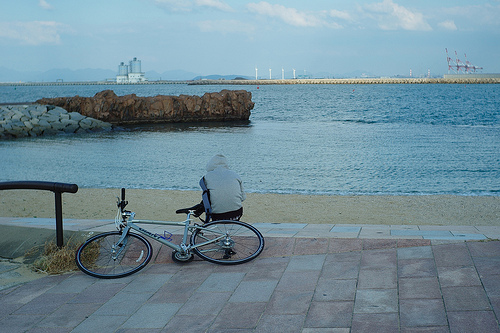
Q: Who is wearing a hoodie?
A: A person.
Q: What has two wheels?
A: A bicycle.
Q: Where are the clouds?
A: In the sky.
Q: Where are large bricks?
A: On the ground.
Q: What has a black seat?
A: The bicycle.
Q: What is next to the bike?
A: A railing.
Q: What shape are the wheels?
A: Round.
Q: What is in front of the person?
A: Sand.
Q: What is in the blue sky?
A: Clouds.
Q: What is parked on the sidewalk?
A: Bicycle.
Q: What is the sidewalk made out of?
A: Brick.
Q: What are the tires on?
A: Bike.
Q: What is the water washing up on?
A: Sand.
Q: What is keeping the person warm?
A: Sweatshirt.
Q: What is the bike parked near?
A: Railing.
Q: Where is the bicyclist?
A: Beach.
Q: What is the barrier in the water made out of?
A: Rocks.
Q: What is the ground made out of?
A: Bricks.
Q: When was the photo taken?
A: Daytime.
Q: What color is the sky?
A: Blue.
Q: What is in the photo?
A: A bicycle.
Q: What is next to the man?
A: A bike.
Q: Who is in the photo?
A: A man.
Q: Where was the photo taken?
A: On a beach.